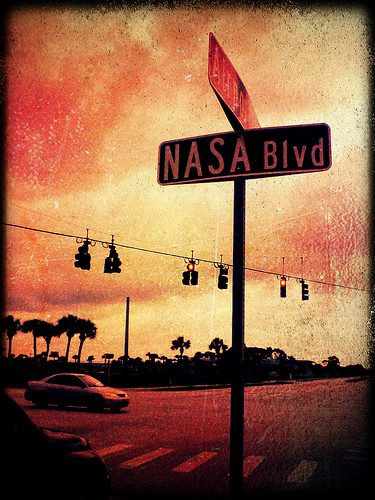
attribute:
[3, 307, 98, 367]
trees — tall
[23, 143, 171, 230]
sky — yellow, orange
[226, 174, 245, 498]
pole — under 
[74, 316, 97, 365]
tree — leafy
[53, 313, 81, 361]
tree — leafy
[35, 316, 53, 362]
tree — leafy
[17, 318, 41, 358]
tree — leafy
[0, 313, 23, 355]
tree — leafy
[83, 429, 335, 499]
paint — white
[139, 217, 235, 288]
traffic signal — hanging 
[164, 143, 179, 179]
n — a letter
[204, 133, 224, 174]
letter — S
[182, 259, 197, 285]
traffic signal — hanging 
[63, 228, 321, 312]
stoplights — above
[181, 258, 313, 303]
red lights — shining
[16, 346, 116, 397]
car — driving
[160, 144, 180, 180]
letters — capital letter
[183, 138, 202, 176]
letters — capital letter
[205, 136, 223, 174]
letters — capital letter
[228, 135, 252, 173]
letters — capital letter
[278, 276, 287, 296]
light — above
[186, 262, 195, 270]
light — on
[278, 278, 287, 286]
light — on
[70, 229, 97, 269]
traffic signal — hanging 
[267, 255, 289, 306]
traffic signal — hanging 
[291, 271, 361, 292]
traffic signal — hanging 